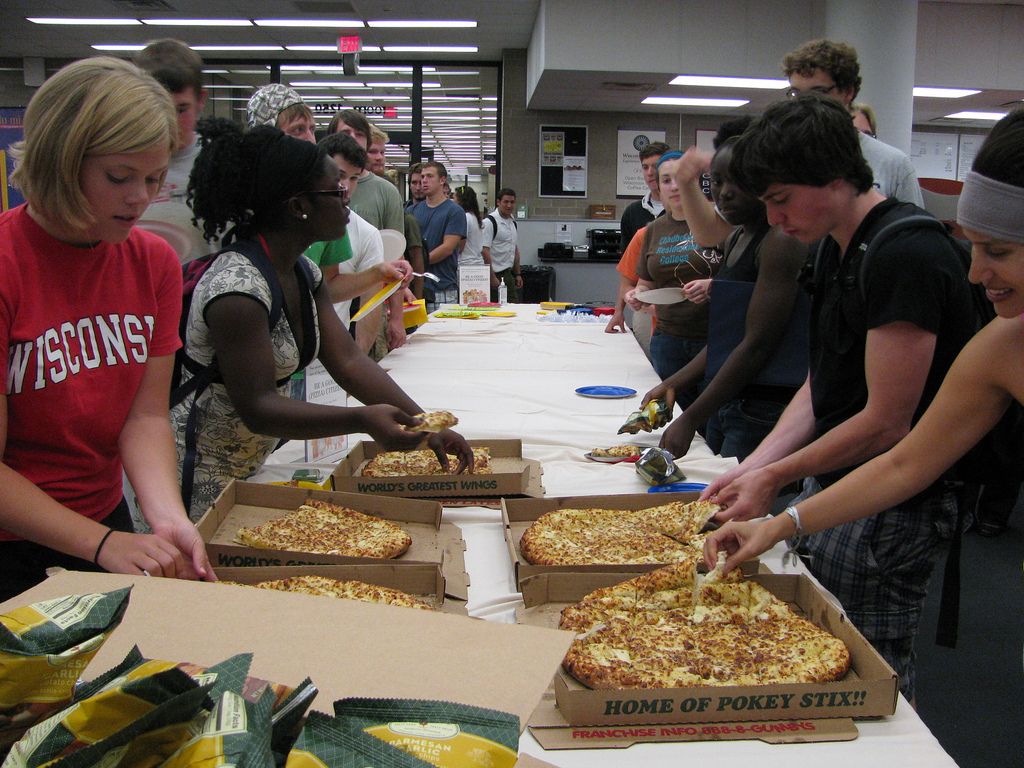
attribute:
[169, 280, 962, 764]
table — long, white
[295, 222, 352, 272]
shirt — green 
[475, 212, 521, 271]
shirt — white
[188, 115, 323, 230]
hair — black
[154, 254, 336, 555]
dress — black, white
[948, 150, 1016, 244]
grey headband — Grey 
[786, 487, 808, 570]
silver bracelet — Silver 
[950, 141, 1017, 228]
grey headband — grey 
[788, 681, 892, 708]
green word — STIX!!, Green 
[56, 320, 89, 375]
white c — White 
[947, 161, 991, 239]
band — gray, head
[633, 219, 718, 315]
shirt — brown, blue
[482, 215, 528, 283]
shirt — white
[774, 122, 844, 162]
hair — dark